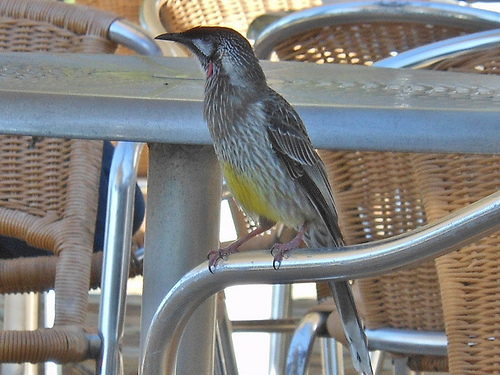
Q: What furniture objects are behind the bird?
A: Chairs.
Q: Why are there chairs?
A: For sitting.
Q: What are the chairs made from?
A: Rattan.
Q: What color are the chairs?
A: Brown.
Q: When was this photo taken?
A: Daytime.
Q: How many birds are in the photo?
A: One.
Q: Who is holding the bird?
A: No one.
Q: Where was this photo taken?
A: At a sitting area.